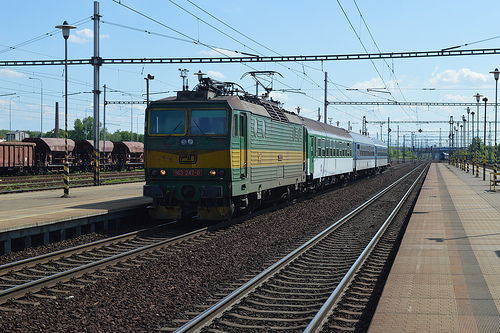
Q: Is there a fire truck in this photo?
A: No, there are no fire trucks.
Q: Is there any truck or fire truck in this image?
A: No, there are no fire trucks or trucks.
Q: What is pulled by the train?
A: The car is pulled by the train.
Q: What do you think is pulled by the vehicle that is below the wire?
A: The car is pulled by the train.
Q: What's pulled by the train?
A: The car is pulled by the train.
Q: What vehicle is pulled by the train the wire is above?
A: The vehicle is a car.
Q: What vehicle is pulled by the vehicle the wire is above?
A: The vehicle is a car.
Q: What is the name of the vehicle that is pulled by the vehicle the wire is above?
A: The vehicle is a car.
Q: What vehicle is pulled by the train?
A: The vehicle is a car.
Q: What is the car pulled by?
A: The car is pulled by the train.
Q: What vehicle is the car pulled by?
A: The car is pulled by the train.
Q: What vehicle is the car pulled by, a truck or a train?
A: The car is pulled by a train.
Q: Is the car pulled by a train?
A: Yes, the car is pulled by a train.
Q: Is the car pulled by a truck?
A: No, the car is pulled by a train.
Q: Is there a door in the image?
A: Yes, there is a door.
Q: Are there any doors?
A: Yes, there is a door.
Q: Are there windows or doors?
A: Yes, there is a door.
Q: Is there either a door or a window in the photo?
A: Yes, there is a door.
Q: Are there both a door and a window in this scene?
A: Yes, there are both a door and a window.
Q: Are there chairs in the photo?
A: No, there are no chairs.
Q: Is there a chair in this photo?
A: No, there are no chairs.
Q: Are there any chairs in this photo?
A: No, there are no chairs.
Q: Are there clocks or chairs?
A: No, there are no chairs or clocks.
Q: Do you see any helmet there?
A: No, there are no helmets.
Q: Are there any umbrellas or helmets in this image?
A: No, there are no helmets or umbrellas.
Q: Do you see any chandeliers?
A: No, there are no chandeliers.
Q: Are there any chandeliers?
A: No, there are no chandeliers.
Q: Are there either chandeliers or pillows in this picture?
A: No, there are no chandeliers or pillows.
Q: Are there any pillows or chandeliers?
A: No, there are no chandeliers or pillows.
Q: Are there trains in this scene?
A: Yes, there is a train.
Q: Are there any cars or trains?
A: Yes, there is a train.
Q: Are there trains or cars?
A: Yes, there is a train.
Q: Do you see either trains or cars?
A: Yes, there is a train.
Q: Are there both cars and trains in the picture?
A: Yes, there are both a train and cars.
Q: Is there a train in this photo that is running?
A: Yes, there is a train that is running.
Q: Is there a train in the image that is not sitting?
A: Yes, there is a train that is running.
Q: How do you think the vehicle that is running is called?
A: The vehicle is a train.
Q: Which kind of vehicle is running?
A: The vehicle is a train.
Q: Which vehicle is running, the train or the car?
A: The train is running.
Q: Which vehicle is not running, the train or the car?
A: The car is not running.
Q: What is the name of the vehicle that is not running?
A: The vehicle is a car.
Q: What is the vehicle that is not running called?
A: The vehicle is a car.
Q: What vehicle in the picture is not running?
A: The vehicle is a car.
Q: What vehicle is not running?
A: The vehicle is a car.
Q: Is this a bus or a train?
A: This is a train.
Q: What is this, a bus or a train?
A: This is a train.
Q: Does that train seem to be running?
A: Yes, the train is running.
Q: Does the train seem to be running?
A: Yes, the train is running.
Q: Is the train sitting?
A: No, the train is running.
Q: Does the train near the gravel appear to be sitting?
A: No, the train is running.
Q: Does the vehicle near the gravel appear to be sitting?
A: No, the train is running.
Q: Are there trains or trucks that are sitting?
A: No, there is a train but it is running.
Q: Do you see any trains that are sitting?
A: No, there is a train but it is running.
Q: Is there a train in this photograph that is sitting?
A: No, there is a train but it is running.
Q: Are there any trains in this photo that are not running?
A: No, there is a train but it is running.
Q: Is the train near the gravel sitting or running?
A: The train is running.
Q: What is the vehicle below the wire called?
A: The vehicle is a train.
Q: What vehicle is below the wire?
A: The vehicle is a train.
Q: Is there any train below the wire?
A: Yes, there is a train below the wire.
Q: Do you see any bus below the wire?
A: No, there is a train below the wire.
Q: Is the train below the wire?
A: Yes, the train is below the wire.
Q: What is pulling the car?
A: The train is pulling the car.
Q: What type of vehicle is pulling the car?
A: The vehicle is a train.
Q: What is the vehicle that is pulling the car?
A: The vehicle is a train.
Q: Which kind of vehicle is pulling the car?
A: The vehicle is a train.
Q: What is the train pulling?
A: The train is pulling the car.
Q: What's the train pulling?
A: The train is pulling the car.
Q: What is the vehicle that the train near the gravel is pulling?
A: The vehicle is a car.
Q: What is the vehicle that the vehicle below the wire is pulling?
A: The vehicle is a car.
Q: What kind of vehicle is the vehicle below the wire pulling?
A: The train is pulling the car.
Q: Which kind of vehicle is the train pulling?
A: The train is pulling the car.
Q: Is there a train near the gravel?
A: Yes, there is a train near the gravel.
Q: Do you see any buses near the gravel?
A: No, there is a train near the gravel.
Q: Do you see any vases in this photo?
A: No, there are no vases.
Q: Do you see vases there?
A: No, there are no vases.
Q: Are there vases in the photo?
A: No, there are no vases.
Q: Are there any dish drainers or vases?
A: No, there are no vases or dish drainers.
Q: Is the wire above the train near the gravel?
A: Yes, the wire is above the train.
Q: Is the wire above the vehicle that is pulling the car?
A: Yes, the wire is above the train.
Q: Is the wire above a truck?
A: No, the wire is above the train.